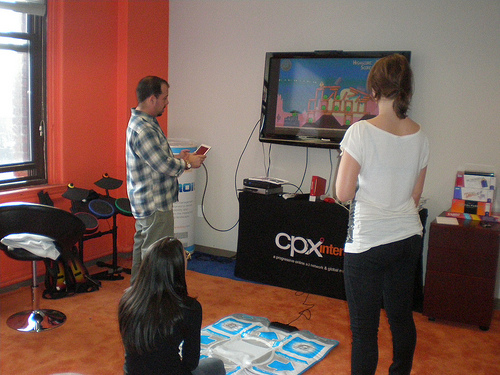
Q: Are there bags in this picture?
A: No, there are no bags.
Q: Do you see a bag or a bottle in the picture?
A: No, there are no bags or bottles.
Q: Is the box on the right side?
A: Yes, the box is on the right of the image.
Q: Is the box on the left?
A: No, the box is on the right of the image.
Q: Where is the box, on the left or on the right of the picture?
A: The box is on the right of the image.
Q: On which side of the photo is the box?
A: The box is on the right of the image.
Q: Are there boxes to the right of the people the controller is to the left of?
A: Yes, there is a box to the right of the people.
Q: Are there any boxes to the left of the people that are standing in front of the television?
A: No, the box is to the right of the people.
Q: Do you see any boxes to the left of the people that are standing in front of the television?
A: No, the box is to the right of the people.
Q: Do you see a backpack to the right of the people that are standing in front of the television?
A: No, there is a box to the right of the people.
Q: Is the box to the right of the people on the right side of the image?
A: Yes, the box is to the right of the people.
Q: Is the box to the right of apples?
A: No, the box is to the right of the people.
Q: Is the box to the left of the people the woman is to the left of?
A: No, the box is to the right of the people.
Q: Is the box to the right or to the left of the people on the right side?
A: The box is to the right of the people.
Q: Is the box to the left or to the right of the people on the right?
A: The box is to the right of the people.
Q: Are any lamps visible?
A: No, there are no lamps.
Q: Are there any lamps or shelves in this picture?
A: No, there are no lamps or shelves.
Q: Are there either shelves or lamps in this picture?
A: No, there are no lamps or shelves.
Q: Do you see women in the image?
A: Yes, there is a woman.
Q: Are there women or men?
A: Yes, there is a woman.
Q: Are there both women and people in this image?
A: Yes, there are both a woman and a person.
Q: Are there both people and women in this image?
A: Yes, there are both a woman and a person.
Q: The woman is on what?
A: The woman is on the carpet.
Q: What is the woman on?
A: The woman is on the carpet.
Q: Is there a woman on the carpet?
A: Yes, there is a woman on the carpet.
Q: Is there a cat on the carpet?
A: No, there is a woman on the carpet.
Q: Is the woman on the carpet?
A: Yes, the woman is on the carpet.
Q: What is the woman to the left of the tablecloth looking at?
A: The woman is looking at the TV.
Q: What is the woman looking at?
A: The woman is looking at the TV.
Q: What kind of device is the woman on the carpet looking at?
A: The woman is looking at the TV.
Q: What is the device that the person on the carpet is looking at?
A: The device is a television.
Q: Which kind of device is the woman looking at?
A: The woman is looking at the TV.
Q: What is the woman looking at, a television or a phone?
A: The woman is looking at a television.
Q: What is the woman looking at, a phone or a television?
A: The woman is looking at a television.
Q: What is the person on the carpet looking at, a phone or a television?
A: The woman is looking at a television.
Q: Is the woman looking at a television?
A: Yes, the woman is looking at a television.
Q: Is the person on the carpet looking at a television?
A: Yes, the woman is looking at a television.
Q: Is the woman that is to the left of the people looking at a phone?
A: No, the woman is looking at a television.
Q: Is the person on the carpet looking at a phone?
A: No, the woman is looking at a television.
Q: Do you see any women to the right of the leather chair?
A: Yes, there is a woman to the right of the chair.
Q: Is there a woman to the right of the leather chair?
A: Yes, there is a woman to the right of the chair.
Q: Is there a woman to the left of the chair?
A: No, the woman is to the right of the chair.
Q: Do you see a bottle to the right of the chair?
A: No, there is a woman to the right of the chair.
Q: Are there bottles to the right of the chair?
A: No, there is a woman to the right of the chair.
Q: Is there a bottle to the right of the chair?
A: No, there is a woman to the right of the chair.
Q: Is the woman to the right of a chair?
A: Yes, the woman is to the right of a chair.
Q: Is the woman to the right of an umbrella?
A: No, the woman is to the right of a chair.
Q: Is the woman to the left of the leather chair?
A: No, the woman is to the right of the chair.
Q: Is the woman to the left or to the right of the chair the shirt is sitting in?
A: The woman is to the right of the chair.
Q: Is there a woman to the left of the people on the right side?
A: Yes, there is a woman to the left of the people.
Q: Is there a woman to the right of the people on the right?
A: No, the woman is to the left of the people.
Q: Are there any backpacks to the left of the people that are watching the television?
A: No, there is a woman to the left of the people.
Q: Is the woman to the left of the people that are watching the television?
A: Yes, the woman is to the left of the people.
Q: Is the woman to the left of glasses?
A: No, the woman is to the left of the people.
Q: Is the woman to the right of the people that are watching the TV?
A: No, the woman is to the left of the people.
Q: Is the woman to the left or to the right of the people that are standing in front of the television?
A: The woman is to the left of the people.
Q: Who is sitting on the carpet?
A: The woman is sitting on the carpet.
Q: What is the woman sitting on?
A: The woman is sitting on the carpet.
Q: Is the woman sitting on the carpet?
A: Yes, the woman is sitting on the carpet.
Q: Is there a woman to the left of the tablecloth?
A: Yes, there is a woman to the left of the tablecloth.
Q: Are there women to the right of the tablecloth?
A: No, the woman is to the left of the tablecloth.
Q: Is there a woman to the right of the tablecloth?
A: No, the woman is to the left of the tablecloth.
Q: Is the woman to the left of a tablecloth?
A: Yes, the woman is to the left of a tablecloth.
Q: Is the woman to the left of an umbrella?
A: No, the woman is to the left of a tablecloth.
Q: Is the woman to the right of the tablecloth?
A: No, the woman is to the left of the tablecloth.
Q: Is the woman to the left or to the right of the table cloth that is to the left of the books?
A: The woman is to the left of the tablecloth.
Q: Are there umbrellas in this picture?
A: No, there are no umbrellas.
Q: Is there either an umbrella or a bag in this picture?
A: No, there are no umbrellas or bags.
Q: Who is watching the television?
A: The people are watching the television.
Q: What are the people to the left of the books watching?
A: The people are watching the television.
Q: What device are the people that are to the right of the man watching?
A: The people are watching the television.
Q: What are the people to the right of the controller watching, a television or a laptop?
A: The people are watching a television.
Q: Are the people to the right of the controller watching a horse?
A: No, the people are watching the television.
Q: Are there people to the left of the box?
A: Yes, there are people to the left of the box.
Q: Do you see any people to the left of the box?
A: Yes, there are people to the left of the box.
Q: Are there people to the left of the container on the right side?
A: Yes, there are people to the left of the box.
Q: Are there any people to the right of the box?
A: No, the people are to the left of the box.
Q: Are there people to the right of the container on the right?
A: No, the people are to the left of the box.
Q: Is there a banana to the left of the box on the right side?
A: No, there are people to the left of the box.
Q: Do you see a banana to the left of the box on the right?
A: No, there are people to the left of the box.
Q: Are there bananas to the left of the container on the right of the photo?
A: No, there are people to the left of the box.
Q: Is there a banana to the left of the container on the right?
A: No, there are people to the left of the box.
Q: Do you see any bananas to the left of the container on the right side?
A: No, there are people to the left of the box.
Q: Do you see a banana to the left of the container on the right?
A: No, there are people to the left of the box.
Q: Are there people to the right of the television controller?
A: Yes, there are people to the right of the controller.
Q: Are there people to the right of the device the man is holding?
A: Yes, there are people to the right of the controller.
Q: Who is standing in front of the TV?
A: The people are standing in front of the TV.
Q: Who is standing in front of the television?
A: The people are standing in front of the TV.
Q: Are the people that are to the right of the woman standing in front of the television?
A: Yes, the people are standing in front of the television.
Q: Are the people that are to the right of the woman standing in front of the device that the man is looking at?
A: Yes, the people are standing in front of the television.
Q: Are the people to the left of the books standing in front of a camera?
A: No, the people are standing in front of the television.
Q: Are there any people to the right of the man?
A: Yes, there are people to the right of the man.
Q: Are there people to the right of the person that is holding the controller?
A: Yes, there are people to the right of the man.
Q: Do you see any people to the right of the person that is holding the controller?
A: Yes, there are people to the right of the man.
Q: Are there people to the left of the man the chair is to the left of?
A: No, the people are to the right of the man.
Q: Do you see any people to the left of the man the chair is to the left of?
A: No, the people are to the right of the man.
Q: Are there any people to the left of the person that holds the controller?
A: No, the people are to the right of the man.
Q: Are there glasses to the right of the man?
A: No, there are people to the right of the man.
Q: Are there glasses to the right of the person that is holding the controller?
A: No, there are people to the right of the man.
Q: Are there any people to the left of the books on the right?
A: Yes, there are people to the left of the books.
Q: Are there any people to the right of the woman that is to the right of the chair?
A: Yes, there are people to the right of the woman.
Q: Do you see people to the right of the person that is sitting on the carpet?
A: Yes, there are people to the right of the woman.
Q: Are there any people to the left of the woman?
A: No, the people are to the right of the woman.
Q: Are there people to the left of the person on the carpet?
A: No, the people are to the right of the woman.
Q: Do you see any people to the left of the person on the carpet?
A: No, the people are to the right of the woman.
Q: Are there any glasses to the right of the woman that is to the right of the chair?
A: No, there are people to the right of the woman.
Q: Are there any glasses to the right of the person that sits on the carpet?
A: No, there are people to the right of the woman.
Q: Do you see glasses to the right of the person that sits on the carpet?
A: No, there are people to the right of the woman.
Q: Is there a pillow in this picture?
A: No, there are no pillows.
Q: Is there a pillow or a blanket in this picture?
A: No, there are no pillows or blankets.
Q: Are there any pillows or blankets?
A: No, there are no pillows or blankets.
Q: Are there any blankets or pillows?
A: No, there are no pillows or blankets.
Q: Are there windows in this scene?
A: Yes, there is a window.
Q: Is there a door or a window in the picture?
A: Yes, there is a window.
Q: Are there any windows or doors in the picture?
A: Yes, there is a window.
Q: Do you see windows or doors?
A: Yes, there is a window.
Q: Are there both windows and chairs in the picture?
A: Yes, there are both a window and a chair.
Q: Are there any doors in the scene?
A: No, there are no doors.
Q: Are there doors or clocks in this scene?
A: No, there are no doors or clocks.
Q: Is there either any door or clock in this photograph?
A: No, there are no doors or clocks.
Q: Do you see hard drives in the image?
A: No, there are no hard drives.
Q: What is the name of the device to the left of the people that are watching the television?
A: The device is a controller.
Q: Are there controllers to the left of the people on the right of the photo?
A: Yes, there is a controller to the left of the people.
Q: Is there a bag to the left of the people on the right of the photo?
A: No, there is a controller to the left of the people.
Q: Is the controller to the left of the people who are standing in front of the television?
A: Yes, the controller is to the left of the people.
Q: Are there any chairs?
A: Yes, there is a chair.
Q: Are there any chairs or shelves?
A: Yes, there is a chair.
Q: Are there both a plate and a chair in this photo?
A: No, there is a chair but no plates.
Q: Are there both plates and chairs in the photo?
A: No, there is a chair but no plates.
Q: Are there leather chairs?
A: Yes, there is a chair that is made of leather.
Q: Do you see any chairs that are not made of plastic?
A: Yes, there is a chair that is made of leather.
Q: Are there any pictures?
A: No, there are no pictures.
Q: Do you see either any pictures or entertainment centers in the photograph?
A: No, there are no pictures or entertainment centers.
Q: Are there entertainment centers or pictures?
A: No, there are no pictures or entertainment centers.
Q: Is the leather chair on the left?
A: Yes, the chair is on the left of the image.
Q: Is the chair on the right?
A: No, the chair is on the left of the image.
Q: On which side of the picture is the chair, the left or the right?
A: The chair is on the left of the image.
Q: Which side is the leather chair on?
A: The chair is on the left of the image.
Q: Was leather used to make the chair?
A: Yes, the chair is made of leather.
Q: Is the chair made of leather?
A: Yes, the chair is made of leather.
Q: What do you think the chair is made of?
A: The chair is made of leather.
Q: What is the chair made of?
A: The chair is made of leather.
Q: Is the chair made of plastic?
A: No, the chair is made of leather.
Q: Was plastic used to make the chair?
A: No, the chair is made of leather.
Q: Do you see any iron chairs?
A: No, there is a chair but it is made of leather.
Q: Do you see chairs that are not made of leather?
A: No, there is a chair but it is made of leather.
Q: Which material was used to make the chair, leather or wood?
A: The chair is made of leather.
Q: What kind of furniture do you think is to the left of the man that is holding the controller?
A: The piece of furniture is a chair.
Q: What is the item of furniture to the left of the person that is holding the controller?
A: The piece of furniture is a chair.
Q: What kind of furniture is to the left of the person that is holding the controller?
A: The piece of furniture is a chair.